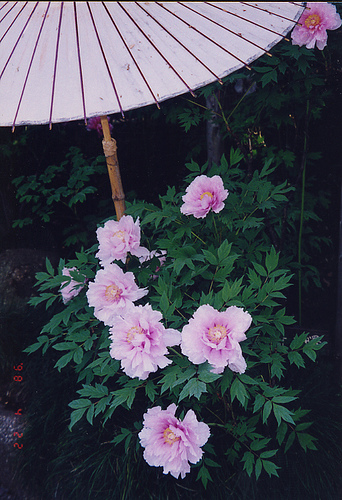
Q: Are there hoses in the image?
A: No, there are no hoses.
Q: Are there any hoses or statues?
A: No, there are no hoses or statues.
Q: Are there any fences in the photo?
A: No, there are no fences.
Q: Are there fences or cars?
A: No, there are no fences or cars.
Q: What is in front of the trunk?
A: The tree is in front of the trunk.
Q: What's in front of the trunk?
A: The tree is in front of the trunk.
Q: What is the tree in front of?
A: The tree is in front of the trunk.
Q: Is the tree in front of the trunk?
A: Yes, the tree is in front of the trunk.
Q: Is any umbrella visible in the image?
A: Yes, there is an umbrella.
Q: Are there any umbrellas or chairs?
A: Yes, there is an umbrella.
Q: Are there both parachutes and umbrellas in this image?
A: No, there is an umbrella but no parachutes.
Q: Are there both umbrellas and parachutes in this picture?
A: No, there is an umbrella but no parachutes.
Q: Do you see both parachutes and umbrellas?
A: No, there is an umbrella but no parachutes.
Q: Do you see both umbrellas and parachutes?
A: No, there is an umbrella but no parachutes.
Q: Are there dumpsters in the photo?
A: No, there are no dumpsters.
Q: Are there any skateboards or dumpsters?
A: No, there are no dumpsters or skateboards.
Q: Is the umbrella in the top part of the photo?
A: Yes, the umbrella is in the top of the image.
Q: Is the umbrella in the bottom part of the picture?
A: No, the umbrella is in the top of the image.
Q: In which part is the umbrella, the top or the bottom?
A: The umbrella is in the top of the image.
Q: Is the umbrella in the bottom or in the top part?
A: The umbrella is in the top of the image.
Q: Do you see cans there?
A: No, there are no cans.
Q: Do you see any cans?
A: No, there are no cans.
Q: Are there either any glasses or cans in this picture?
A: No, there are no cans or glasses.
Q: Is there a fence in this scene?
A: No, there are no fences.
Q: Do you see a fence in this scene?
A: No, there are no fences.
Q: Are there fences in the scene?
A: No, there are no fences.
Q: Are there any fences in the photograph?
A: No, there are no fences.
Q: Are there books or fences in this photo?
A: No, there are no fences or books.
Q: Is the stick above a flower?
A: Yes, the stick is above a flower.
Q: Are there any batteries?
A: No, there are no batteries.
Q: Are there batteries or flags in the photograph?
A: No, there are no batteries or flags.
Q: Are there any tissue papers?
A: No, there are no tissue papers.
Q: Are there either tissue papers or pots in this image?
A: No, there are no tissue papers or pots.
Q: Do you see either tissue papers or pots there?
A: No, there are no tissue papers or pots.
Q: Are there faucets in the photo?
A: No, there are no faucets.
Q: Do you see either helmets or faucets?
A: No, there are no faucets or helmets.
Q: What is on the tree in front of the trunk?
A: The flower is on the tree.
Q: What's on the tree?
A: The flower is on the tree.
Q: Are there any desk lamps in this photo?
A: No, there are no desk lamps.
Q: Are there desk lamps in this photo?
A: No, there are no desk lamps.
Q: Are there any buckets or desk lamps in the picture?
A: No, there are no desk lamps or buckets.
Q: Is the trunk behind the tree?
A: Yes, the trunk is behind the tree.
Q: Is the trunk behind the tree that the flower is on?
A: Yes, the trunk is behind the tree.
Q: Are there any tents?
A: No, there are no tents.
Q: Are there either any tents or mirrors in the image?
A: No, there are no tents or mirrors.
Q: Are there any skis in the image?
A: No, there are no skis.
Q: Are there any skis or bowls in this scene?
A: No, there are no skis or bowls.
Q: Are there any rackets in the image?
A: No, there are no rackets.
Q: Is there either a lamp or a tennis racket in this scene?
A: No, there are no rackets or lamps.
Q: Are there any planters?
A: No, there are no planters.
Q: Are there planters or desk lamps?
A: No, there are no planters or desk lamps.